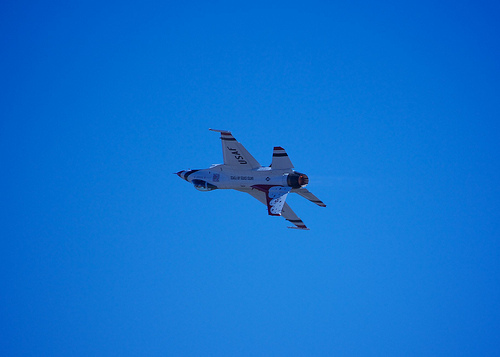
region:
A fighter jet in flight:
[138, 84, 374, 259]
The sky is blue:
[22, 233, 497, 355]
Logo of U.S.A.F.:
[225, 144, 247, 167]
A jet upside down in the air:
[161, 113, 338, 240]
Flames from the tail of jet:
[287, 168, 312, 190]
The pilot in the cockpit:
[189, 177, 215, 193]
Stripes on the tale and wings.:
[280, 192, 331, 239]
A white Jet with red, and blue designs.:
[166, 121, 341, 241]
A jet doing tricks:
[155, 105, 370, 280]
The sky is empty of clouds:
[5, 8, 146, 314]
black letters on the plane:
[223, 140, 248, 171]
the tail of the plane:
[261, 181, 290, 222]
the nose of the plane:
[168, 161, 193, 184]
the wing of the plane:
[206, 119, 263, 168]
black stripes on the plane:
[269, 141, 289, 159]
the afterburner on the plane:
[286, 166, 311, 192]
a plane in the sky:
[163, 123, 330, 234]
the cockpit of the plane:
[190, 175, 217, 193]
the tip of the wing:
[206, 121, 236, 137]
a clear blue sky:
[0, 0, 499, 355]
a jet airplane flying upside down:
[177, 127, 327, 230]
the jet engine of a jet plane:
[287, 168, 310, 189]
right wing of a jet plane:
[211, 127, 261, 167]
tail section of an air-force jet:
[267, 140, 323, 215]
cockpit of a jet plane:
[172, 160, 217, 190]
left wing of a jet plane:
[240, 185, 305, 226]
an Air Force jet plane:
[176, 126, 328, 232]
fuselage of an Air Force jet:
[210, 165, 308, 190]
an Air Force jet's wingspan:
[212, 127, 309, 232]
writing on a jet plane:
[223, 143, 249, 169]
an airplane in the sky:
[139, 127, 334, 242]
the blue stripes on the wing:
[210, 119, 232, 143]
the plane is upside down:
[160, 100, 371, 270]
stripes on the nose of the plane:
[169, 161, 194, 183]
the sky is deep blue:
[8, 8, 493, 340]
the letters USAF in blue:
[217, 141, 261, 169]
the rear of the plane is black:
[277, 169, 312, 191]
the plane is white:
[161, 105, 325, 238]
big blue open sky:
[13, 10, 496, 350]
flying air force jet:
[181, 106, 338, 256]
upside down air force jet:
[170, 119, 338, 272]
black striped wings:
[161, 112, 331, 232]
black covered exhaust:
[276, 167, 316, 207]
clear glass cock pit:
[188, 173, 219, 198]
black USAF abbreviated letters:
[215, 145, 255, 180]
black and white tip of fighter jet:
[160, 167, 203, 190]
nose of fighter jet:
[160, 155, 225, 210]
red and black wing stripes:
[277, 211, 317, 238]